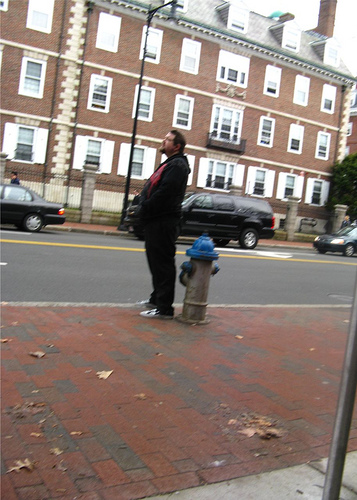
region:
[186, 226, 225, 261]
a blue top on a fie hydrant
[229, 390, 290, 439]
a pile of dead leaves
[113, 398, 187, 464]
red bricks in the sidewalk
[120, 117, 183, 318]
a man standin on the curb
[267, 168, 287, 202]
white shutters around a window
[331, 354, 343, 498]
a metal pole in the sidewalk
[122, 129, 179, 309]
a man wearing a black hoodie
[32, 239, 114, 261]
yellow line marking the road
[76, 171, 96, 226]
a stone column supporting the fence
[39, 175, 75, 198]
a black iron fence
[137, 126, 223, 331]
man standing next to fire hydrant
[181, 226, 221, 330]
gray and blue fire hydrant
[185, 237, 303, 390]
fire hydrant on brick walkway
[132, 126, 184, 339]
man standing on red brick walkway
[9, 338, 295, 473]
leaves on brick sidewalk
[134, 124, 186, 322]
man with black jacket on sidewalk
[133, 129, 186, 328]
man with black pants on sidewalk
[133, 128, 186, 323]
man wearing blue and white tennis shoes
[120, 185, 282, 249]
SUV parked across the street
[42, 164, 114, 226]
stone and metal fencing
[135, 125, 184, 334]
Man eyeglasses looking upward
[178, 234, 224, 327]
Fire hydrant gray and blue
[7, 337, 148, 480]
Fallen leaves red brick sidewalk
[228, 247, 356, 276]
White arrow yellow lane markings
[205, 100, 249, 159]
Iron balcony under window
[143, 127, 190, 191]
Man facial hair red shirt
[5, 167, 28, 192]
Person walking sidewalk background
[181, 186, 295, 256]
Black SUV flowing traffic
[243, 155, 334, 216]
Lower level white shutters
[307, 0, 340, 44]
Tall chimney high roof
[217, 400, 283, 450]
brown leaf is on the ground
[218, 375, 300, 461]
brown leaf is on the ground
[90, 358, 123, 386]
brown leaf is on the ground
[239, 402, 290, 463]
brown leaf is on the ground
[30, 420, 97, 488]
brown leaf is on the ground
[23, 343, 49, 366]
brown leaf is on the ground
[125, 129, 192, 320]
man is standing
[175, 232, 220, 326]
grey and blue fire hydrant behind man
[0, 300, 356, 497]
side walk is brick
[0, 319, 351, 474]
leaves on sidewalk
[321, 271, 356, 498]
pole in front of sidewalk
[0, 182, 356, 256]
cars parked on road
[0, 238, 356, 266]
yellow line on road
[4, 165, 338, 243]
black metal fence behind cars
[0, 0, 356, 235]
old fancy apartment building behind fence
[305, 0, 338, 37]
brick chimney on building